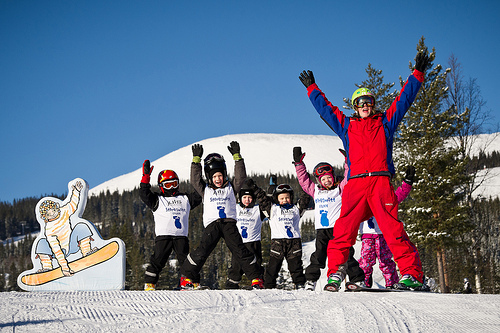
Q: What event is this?
A: Snowboard.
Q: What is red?
A: Suit.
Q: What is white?
A: Snow.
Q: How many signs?
A: One.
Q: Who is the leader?
A: The one in red.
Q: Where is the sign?
A: To the left of the crowd.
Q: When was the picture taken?
A: Daytime.